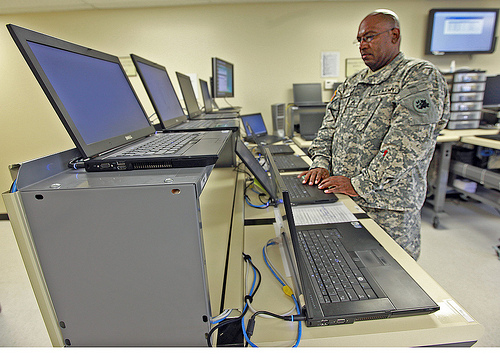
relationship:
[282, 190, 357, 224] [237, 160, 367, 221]
paper on desk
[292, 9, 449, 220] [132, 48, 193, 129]
military member looks at computer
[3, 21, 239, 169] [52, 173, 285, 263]
laptop on stand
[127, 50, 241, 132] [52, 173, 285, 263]
laptop on stand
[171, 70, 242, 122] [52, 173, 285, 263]
laptop on stand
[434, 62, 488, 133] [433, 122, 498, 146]
bin on table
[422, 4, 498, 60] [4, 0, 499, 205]
tv on wall